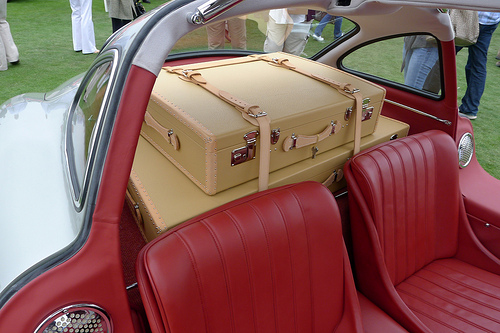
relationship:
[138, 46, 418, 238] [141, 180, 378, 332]
suitcases behind seat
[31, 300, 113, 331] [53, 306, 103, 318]
speaker has top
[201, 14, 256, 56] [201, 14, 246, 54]
partial legs in khaki pants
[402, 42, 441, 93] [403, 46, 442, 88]
leg in jeans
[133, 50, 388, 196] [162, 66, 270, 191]
case has luggage strap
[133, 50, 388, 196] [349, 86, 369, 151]
case has strap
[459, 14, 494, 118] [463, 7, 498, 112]
leg in pants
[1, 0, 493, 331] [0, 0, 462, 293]
car has trunk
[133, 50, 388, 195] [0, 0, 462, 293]
case in trunk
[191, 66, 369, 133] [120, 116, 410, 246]
strap holding down suitcases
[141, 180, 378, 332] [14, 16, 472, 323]
seat in vehicle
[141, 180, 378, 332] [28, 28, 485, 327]
seat in vehicle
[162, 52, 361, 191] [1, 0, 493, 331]
luggage strap in car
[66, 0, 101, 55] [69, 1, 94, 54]
person wearing pants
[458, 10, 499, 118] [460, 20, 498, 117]
person wearing pants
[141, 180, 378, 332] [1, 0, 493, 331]
seat in car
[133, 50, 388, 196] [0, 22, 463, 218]
case in trunk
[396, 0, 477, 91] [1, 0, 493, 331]
people standing behind car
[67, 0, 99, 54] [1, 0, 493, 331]
people standing behind car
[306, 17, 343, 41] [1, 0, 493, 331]
people standing behind car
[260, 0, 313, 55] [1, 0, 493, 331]
people standing behind car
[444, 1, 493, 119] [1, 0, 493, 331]
people standing behind car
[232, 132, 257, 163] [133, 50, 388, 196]
latches on case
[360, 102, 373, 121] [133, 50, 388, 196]
latches on case